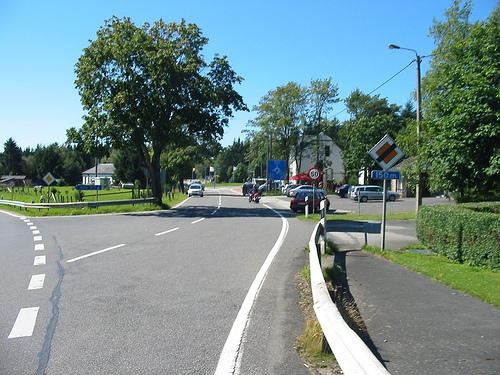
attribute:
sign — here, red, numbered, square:
[305, 164, 322, 215]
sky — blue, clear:
[2, 2, 492, 154]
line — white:
[13, 219, 49, 372]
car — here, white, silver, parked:
[185, 182, 205, 199]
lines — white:
[2, 182, 319, 374]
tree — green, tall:
[78, 13, 240, 202]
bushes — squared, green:
[414, 205, 499, 264]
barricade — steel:
[302, 212, 394, 374]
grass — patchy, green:
[5, 177, 185, 214]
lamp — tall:
[307, 115, 332, 194]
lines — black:
[317, 34, 494, 119]